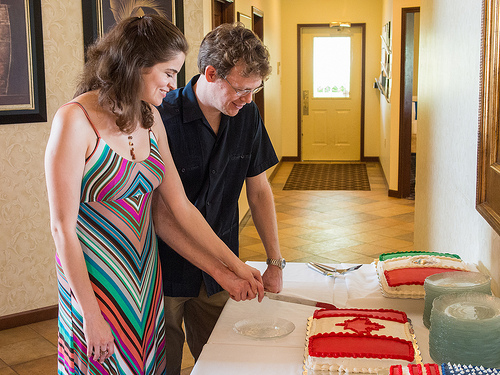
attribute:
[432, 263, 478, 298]
plate — clear, glass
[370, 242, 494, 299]
cake — green, white, red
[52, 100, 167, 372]
dress — striped, spaghetti-strap, colorful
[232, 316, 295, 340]
plate — clear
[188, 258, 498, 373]
cloth — white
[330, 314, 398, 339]
leaf — canadian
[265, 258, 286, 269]
wrist watch — silver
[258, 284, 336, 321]
serving piece — silver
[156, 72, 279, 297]
shirt — black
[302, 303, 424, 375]
cake — red, white, oblong, canadian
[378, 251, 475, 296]
frosting — Mexican flag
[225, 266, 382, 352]
cutting cake — not a noun you idiot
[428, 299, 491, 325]
plate — plastic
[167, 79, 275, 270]
shirt — navy blue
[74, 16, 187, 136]
hair — long, brown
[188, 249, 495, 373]
table — clear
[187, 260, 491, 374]
tablecloth — white